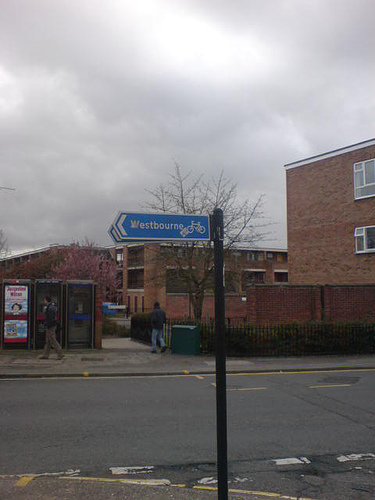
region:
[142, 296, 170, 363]
This is a person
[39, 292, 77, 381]
This is a person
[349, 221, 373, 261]
This is a window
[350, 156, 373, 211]
This is a window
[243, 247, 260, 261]
This is a window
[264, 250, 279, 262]
This is a window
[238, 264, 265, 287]
This is a window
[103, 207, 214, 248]
blue and white street sign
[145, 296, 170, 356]
person walking on the side walk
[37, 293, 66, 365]
person walking on the side walk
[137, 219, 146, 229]
white letter on a blue sign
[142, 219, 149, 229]
white letter on a blue sign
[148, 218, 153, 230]
white letter on a blue sign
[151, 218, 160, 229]
white letter on a blue sign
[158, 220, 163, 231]
white letter on a blue sign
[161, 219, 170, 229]
white letter on a blue sign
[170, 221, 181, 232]
white letter on a blue sign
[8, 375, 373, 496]
the road is gray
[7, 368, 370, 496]
the road has white and yellow markings on it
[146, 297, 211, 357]
the person is walking along the fence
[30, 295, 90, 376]
the person is walking on the side walk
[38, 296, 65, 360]
the guy is wearing brown color pants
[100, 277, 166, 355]
the guy is walking towards an entrance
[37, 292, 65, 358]
the man is turning his head towards his left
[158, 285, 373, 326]
the wall is red in color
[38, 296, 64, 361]
the guy is keeping his hands in his pant pocket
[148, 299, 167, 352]
the person is keeping his hands in his jacket's pocket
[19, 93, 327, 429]
this is a street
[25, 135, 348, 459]
this is an urban area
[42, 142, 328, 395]
this is a city street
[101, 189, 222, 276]
the street sign is blue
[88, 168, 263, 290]
the sign is blue and white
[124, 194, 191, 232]
the writing is white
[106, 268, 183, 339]
the man is walking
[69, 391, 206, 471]
the street is gray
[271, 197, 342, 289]
the building is red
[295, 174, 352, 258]
the building is brick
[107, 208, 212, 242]
a blue and white street sign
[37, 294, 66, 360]
a man walking on a sidewalk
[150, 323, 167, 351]
a man wearing blue jeans